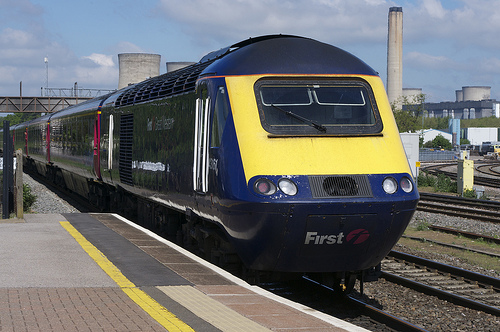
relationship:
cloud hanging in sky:
[1, 1, 44, 21] [1, 0, 496, 101]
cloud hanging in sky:
[0, 29, 27, 48] [1, 0, 496, 101]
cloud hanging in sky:
[1, 63, 77, 83] [1, 0, 496, 101]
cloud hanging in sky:
[148, 0, 438, 47] [1, 0, 496, 101]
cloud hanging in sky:
[152, 0, 499, 86] [1, 0, 496, 101]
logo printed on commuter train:
[303, 226, 370, 246] [1, 33, 420, 295]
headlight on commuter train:
[277, 174, 301, 199] [1, 33, 420, 295]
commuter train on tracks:
[1, 33, 420, 295] [3, 167, 499, 330]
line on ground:
[56, 218, 190, 332] [4, 157, 499, 330]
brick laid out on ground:
[0, 289, 176, 330] [4, 157, 499, 330]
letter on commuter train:
[302, 229, 343, 245] [1, 33, 420, 295]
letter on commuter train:
[334, 229, 344, 243] [1, 33, 420, 295]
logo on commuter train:
[347, 226, 371, 245] [1, 33, 420, 295]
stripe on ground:
[113, 209, 365, 330] [0, 276, 500, 332]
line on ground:
[56, 218, 190, 332] [0, 276, 500, 332]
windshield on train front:
[258, 73, 386, 143] [200, 34, 420, 204]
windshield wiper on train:
[269, 102, 326, 131] [0, 30, 420, 271]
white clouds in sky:
[9, 21, 114, 85] [1, 0, 496, 101]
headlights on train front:
[256, 172, 419, 202] [200, 34, 420, 204]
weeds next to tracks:
[413, 227, 498, 268] [256, 157, 500, 332]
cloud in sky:
[0, 29, 27, 48] [1, 0, 496, 101]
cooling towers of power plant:
[110, 48, 198, 85] [5, 0, 497, 115]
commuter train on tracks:
[1, 30, 421, 277] [254, 261, 496, 329]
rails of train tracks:
[288, 187, 498, 326] [288, 197, 499, 327]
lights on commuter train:
[242, 170, 422, 200] [1, 33, 420, 295]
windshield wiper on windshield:
[257, 98, 326, 136] [248, 70, 384, 138]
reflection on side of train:
[11, 110, 168, 172] [0, 30, 420, 271]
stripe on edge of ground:
[236, 280, 366, 332] [0, 276, 500, 332]